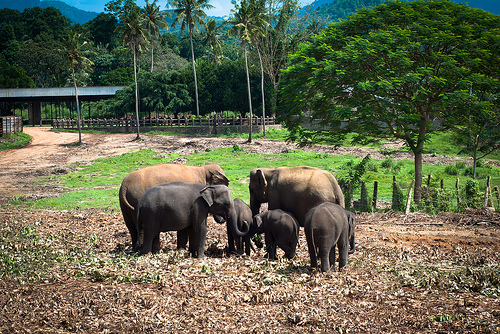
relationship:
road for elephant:
[1, 121, 90, 166] [132, 182, 249, 258]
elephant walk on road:
[132, 182, 249, 258] [1, 121, 90, 166]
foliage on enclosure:
[1, 203, 499, 331] [0, 128, 499, 334]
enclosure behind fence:
[0, 83, 127, 124] [52, 112, 278, 129]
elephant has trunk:
[132, 182, 249, 258] [226, 206, 251, 241]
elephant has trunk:
[245, 165, 347, 215] [248, 190, 261, 218]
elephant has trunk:
[302, 201, 359, 275] [347, 230, 357, 257]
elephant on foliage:
[118, 160, 230, 250] [1, 203, 499, 331]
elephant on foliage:
[132, 182, 249, 258] [1, 203, 499, 331]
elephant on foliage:
[229, 196, 257, 255] [1, 203, 499, 331]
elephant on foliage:
[253, 206, 302, 260] [1, 203, 499, 331]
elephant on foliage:
[245, 165, 347, 215] [1, 203, 499, 331]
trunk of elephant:
[226, 206, 251, 241] [132, 182, 249, 258]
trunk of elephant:
[248, 190, 261, 218] [245, 165, 347, 215]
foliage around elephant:
[1, 203, 499, 331] [118, 160, 230, 250]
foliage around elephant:
[1, 203, 499, 331] [132, 182, 249, 258]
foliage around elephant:
[1, 203, 499, 331] [245, 165, 347, 215]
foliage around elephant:
[1, 203, 499, 331] [302, 201, 359, 275]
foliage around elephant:
[1, 203, 499, 331] [253, 206, 302, 260]